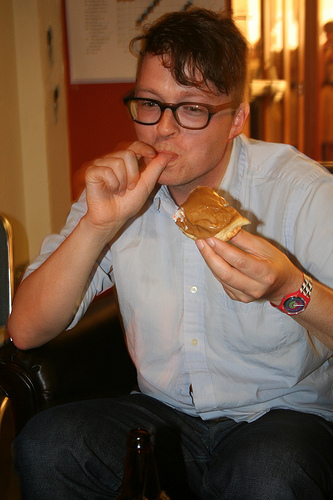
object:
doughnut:
[172, 185, 251, 242]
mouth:
[155, 149, 181, 167]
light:
[247, 0, 261, 48]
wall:
[61, 1, 230, 203]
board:
[66, 0, 232, 86]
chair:
[0, 283, 118, 422]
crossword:
[135, 0, 194, 27]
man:
[6, 5, 333, 499]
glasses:
[122, 90, 242, 130]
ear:
[229, 102, 250, 141]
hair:
[129, 4, 253, 119]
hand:
[80, 141, 174, 227]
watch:
[270, 272, 313, 317]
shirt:
[20, 133, 333, 425]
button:
[190, 286, 198, 294]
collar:
[217, 135, 248, 209]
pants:
[0, 392, 333, 500]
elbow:
[6, 281, 48, 350]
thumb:
[141, 153, 174, 195]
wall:
[12, 0, 51, 267]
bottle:
[122, 421, 161, 499]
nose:
[156, 108, 179, 139]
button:
[192, 338, 198, 346]